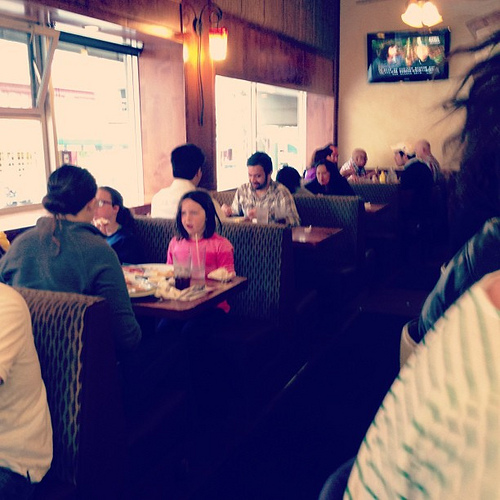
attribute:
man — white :
[376, 142, 438, 254]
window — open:
[2, 15, 61, 122]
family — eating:
[286, 139, 406, 200]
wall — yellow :
[335, 1, 499, 173]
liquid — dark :
[175, 277, 191, 290]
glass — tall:
[171, 245, 192, 288]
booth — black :
[328, 166, 458, 235]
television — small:
[347, 17, 460, 77]